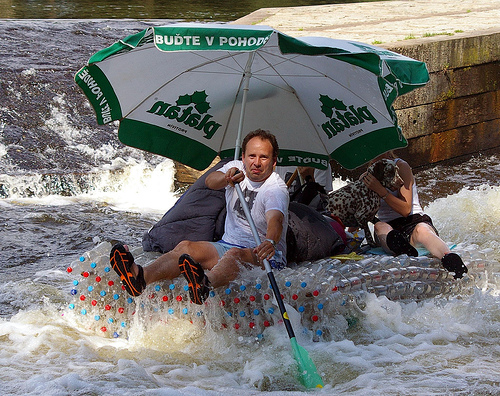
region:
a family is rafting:
[45, 15, 494, 387]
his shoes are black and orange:
[173, 264, 235, 325]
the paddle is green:
[251, 301, 363, 391]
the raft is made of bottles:
[278, 276, 402, 339]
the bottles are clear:
[85, 274, 186, 346]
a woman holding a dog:
[307, 79, 482, 268]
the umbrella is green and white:
[93, 94, 328, 218]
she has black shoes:
[335, 174, 477, 308]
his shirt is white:
[160, 143, 346, 297]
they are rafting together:
[58, 93, 467, 365]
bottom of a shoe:
[148, 247, 205, 340]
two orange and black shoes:
[79, 244, 212, 335]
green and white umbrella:
[116, 69, 402, 151]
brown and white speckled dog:
[313, 153, 421, 270]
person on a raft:
[357, 132, 451, 315]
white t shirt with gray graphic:
[177, 172, 290, 277]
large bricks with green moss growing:
[413, 71, 486, 163]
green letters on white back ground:
[306, 92, 381, 147]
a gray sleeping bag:
[126, 160, 224, 253]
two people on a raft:
[92, 127, 431, 393]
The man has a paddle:
[214, 152, 345, 387]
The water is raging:
[16, 305, 157, 392]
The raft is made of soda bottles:
[230, 262, 462, 357]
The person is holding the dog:
[288, 152, 423, 250]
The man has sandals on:
[96, 183, 259, 370]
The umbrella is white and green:
[58, 23, 497, 208]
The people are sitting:
[271, 125, 433, 289]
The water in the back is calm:
[21, 5, 138, 67]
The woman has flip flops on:
[377, 220, 494, 284]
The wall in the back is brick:
[385, 8, 493, 180]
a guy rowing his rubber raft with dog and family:
[55, 2, 491, 360]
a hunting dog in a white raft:
[320, 160, 405, 247]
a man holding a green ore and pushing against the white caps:
[223, 167, 328, 389]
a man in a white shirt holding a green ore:
[219, 161, 296, 239]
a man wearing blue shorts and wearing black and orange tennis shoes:
[111, 240, 293, 317]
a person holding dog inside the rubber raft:
[358, 152, 481, 283]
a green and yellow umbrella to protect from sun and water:
[76, 15, 420, 172]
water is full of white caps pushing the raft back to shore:
[2, 115, 497, 391]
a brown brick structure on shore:
[236, 5, 490, 159]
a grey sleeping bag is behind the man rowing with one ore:
[154, 155, 341, 253]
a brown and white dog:
[323, 157, 409, 264]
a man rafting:
[181, 127, 315, 362]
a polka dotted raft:
[73, 233, 471, 341]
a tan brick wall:
[373, 28, 488, 173]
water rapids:
[254, 257, 493, 384]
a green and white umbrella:
[64, 67, 431, 164]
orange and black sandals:
[102, 243, 222, 305]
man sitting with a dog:
[333, 147, 483, 279]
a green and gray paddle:
[217, 171, 334, 393]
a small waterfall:
[14, 69, 151, 227]